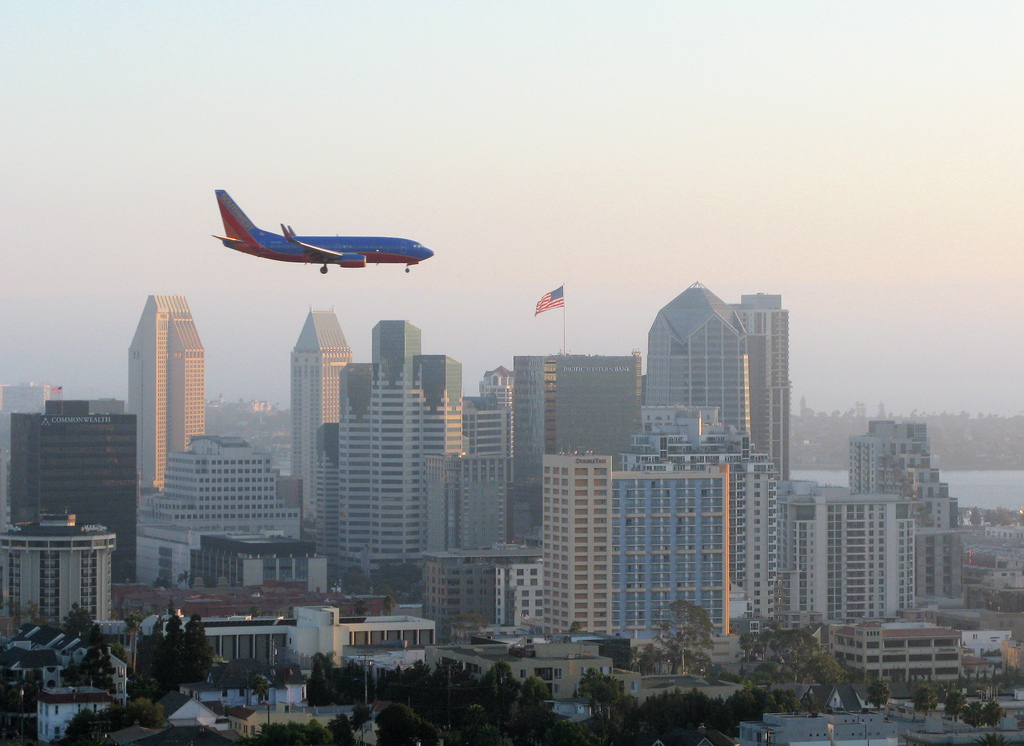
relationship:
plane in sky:
[214, 186, 438, 276] [0, 2, 1022, 407]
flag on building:
[536, 284, 568, 355] [515, 352, 643, 552]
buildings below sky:
[5, 282, 1023, 744] [0, 2, 1022, 407]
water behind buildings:
[794, 468, 1022, 515] [5, 282, 1023, 744]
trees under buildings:
[2, 602, 1023, 741] [5, 282, 1023, 744]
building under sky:
[339, 315, 463, 565] [0, 2, 1022, 407]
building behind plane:
[515, 352, 643, 552] [214, 186, 438, 276]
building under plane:
[515, 352, 643, 552] [214, 186, 438, 276]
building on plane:
[515, 352, 643, 552] [214, 186, 438, 276]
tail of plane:
[216, 189, 265, 252] [214, 186, 438, 276]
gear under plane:
[317, 262, 419, 275] [214, 186, 438, 276]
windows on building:
[375, 371, 407, 558] [339, 315, 463, 565]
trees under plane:
[2, 602, 1023, 741] [214, 186, 438, 276]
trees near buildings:
[2, 602, 1023, 741] [5, 282, 1023, 744]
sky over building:
[0, 2, 1022, 407] [515, 352, 643, 552]